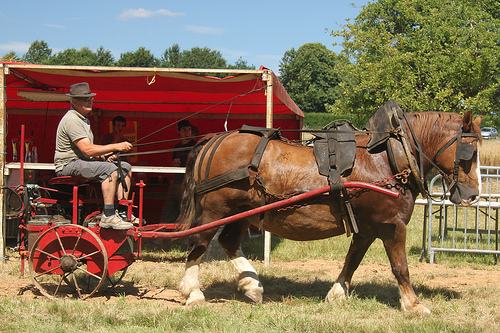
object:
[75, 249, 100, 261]
spoke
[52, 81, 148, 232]
man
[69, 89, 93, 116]
head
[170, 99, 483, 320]
horse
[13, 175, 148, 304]
cart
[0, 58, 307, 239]
tent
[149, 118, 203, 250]
people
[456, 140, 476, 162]
blinder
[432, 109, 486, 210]
head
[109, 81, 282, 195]
bull whip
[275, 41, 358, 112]
trees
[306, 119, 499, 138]
hedge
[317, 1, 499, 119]
trees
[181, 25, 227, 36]
clouds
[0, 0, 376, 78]
sky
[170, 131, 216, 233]
brown tail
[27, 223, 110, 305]
wheel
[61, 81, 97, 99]
top hat